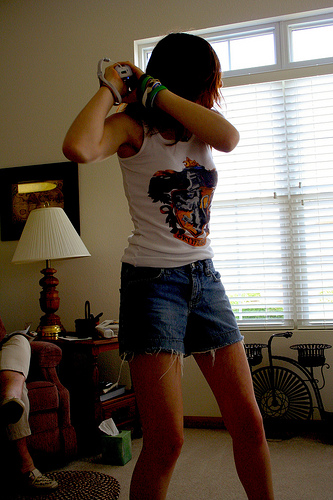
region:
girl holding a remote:
[24, 20, 268, 190]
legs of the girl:
[115, 352, 287, 435]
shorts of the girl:
[120, 264, 258, 364]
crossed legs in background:
[1, 338, 69, 475]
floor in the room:
[189, 457, 228, 496]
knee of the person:
[142, 420, 198, 473]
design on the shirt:
[139, 162, 232, 244]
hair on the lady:
[155, 47, 224, 105]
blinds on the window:
[249, 110, 320, 227]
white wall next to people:
[15, 29, 74, 80]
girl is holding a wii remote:
[94, 40, 149, 108]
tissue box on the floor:
[83, 416, 134, 471]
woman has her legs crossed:
[9, 333, 66, 492]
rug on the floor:
[53, 457, 124, 498]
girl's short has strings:
[128, 313, 271, 383]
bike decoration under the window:
[248, 332, 331, 451]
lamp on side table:
[22, 211, 112, 336]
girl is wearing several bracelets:
[133, 60, 168, 117]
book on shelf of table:
[92, 387, 130, 414]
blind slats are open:
[238, 226, 308, 333]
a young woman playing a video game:
[95, 44, 301, 491]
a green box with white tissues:
[91, 419, 129, 465]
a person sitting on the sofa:
[4, 325, 67, 489]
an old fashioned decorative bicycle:
[264, 330, 322, 444]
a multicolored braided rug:
[73, 476, 106, 498]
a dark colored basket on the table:
[77, 297, 106, 336]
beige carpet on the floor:
[190, 448, 229, 493]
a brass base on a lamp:
[40, 325, 66, 335]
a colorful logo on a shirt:
[150, 154, 216, 245]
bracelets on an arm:
[140, 73, 166, 106]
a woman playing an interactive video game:
[65, 32, 245, 330]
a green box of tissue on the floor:
[85, 418, 135, 463]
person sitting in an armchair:
[0, 309, 61, 493]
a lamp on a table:
[15, 203, 83, 331]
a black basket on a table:
[70, 298, 102, 337]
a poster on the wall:
[1, 162, 85, 235]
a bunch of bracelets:
[138, 74, 169, 112]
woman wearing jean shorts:
[109, 262, 246, 358]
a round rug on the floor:
[33, 459, 116, 498]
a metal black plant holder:
[244, 326, 331, 437]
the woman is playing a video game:
[40, 33, 294, 424]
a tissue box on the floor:
[88, 411, 130, 469]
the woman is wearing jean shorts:
[99, 234, 245, 388]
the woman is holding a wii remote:
[74, 36, 188, 124]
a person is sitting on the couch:
[1, 290, 74, 439]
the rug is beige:
[173, 430, 312, 490]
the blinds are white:
[190, 73, 327, 281]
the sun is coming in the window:
[146, 10, 327, 304]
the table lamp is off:
[0, 177, 85, 342]